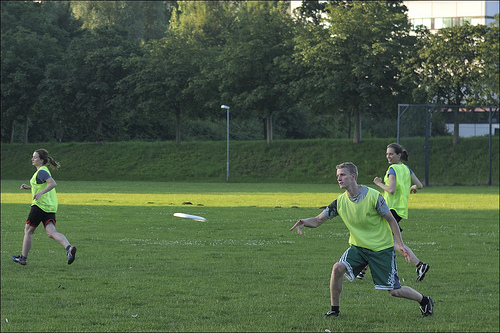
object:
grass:
[0, 178, 500, 333]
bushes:
[1, 134, 498, 185]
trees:
[2, 1, 496, 136]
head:
[336, 162, 358, 189]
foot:
[323, 310, 339, 317]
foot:
[420, 296, 434, 316]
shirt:
[323, 186, 393, 251]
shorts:
[339, 240, 404, 292]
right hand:
[290, 219, 305, 236]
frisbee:
[172, 212, 206, 222]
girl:
[11, 147, 76, 266]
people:
[283, 162, 437, 320]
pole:
[226, 108, 230, 183]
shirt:
[29, 166, 58, 214]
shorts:
[26, 204, 56, 228]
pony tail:
[47, 156, 61, 171]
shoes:
[388, 208, 406, 232]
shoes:
[418, 296, 434, 316]